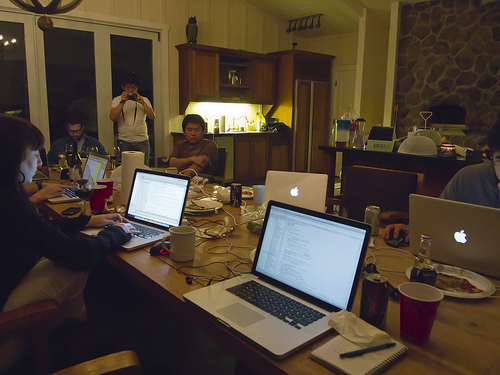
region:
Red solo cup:
[395, 278, 442, 343]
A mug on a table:
[167, 222, 197, 264]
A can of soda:
[360, 268, 387, 328]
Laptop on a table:
[182, 201, 370, 355]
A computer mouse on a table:
[147, 235, 172, 255]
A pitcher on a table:
[334, 116, 351, 147]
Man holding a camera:
[107, 73, 154, 164]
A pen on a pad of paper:
[338, 341, 397, 358]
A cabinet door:
[192, 53, 219, 103]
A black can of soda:
[227, 183, 242, 206]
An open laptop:
[179, 200, 374, 360]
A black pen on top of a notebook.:
[333, 336, 398, 359]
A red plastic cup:
[394, 280, 446, 347]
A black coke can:
[359, 272, 391, 332]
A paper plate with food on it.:
[403, 257, 496, 302]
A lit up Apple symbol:
[451, 228, 473, 248]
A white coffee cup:
[160, 223, 197, 265]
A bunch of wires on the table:
[176, 205, 256, 285]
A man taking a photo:
[108, 76, 158, 165]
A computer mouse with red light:
[148, 240, 175, 257]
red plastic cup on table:
[388, 276, 447, 348]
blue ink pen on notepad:
[330, 335, 397, 362]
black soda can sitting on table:
[354, 274, 394, 329]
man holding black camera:
[103, 77, 165, 159]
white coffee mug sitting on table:
[158, 218, 205, 263]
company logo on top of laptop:
[443, 225, 477, 247]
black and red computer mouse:
[141, 238, 175, 260]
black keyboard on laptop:
[226, 273, 328, 335]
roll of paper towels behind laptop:
[115, 145, 152, 201]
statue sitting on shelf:
[175, 11, 202, 51]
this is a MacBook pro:
[182, 198, 379, 359]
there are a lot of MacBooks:
[23, 108, 490, 328]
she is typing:
[6, 108, 194, 293]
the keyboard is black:
[222, 263, 324, 350]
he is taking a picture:
[87, 43, 184, 172]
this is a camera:
[107, 88, 144, 110]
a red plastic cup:
[395, 263, 450, 358]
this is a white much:
[157, 210, 206, 267]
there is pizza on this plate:
[422, 258, 482, 300]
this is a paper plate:
[397, 249, 494, 306]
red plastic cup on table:
[395, 280, 443, 341]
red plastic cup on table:
[88, 181, 105, 210]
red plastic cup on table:
[96, 176, 113, 196]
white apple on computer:
[451, 223, 470, 248]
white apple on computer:
[288, 183, 303, 198]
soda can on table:
[357, 270, 388, 330]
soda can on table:
[362, 201, 381, 236]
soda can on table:
[229, 181, 241, 207]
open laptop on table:
[177, 200, 372, 365]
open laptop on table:
[76, 166, 193, 255]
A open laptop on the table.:
[185, 195, 355, 359]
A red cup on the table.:
[392, 275, 446, 342]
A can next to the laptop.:
[363, 272, 388, 313]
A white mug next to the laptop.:
[159, 221, 195, 266]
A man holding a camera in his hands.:
[115, 91, 143, 113]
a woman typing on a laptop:
[5, 120, 189, 320]